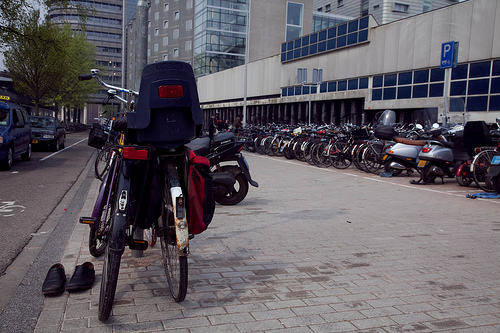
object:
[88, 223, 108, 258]
tire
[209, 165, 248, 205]
tire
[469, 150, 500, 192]
tire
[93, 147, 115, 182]
tire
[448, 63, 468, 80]
window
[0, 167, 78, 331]
road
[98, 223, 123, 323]
tire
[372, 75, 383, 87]
window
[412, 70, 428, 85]
window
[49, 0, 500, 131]
building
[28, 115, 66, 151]
car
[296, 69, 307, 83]
lights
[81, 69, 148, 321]
bicycle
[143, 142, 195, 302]
bicycle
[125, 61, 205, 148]
seat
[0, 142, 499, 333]
ground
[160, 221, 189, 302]
tire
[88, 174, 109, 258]
tire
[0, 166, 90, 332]
street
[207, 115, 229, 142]
man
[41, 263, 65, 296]
shoe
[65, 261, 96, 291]
shoe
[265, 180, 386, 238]
concrete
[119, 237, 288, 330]
shadow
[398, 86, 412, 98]
window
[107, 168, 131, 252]
fender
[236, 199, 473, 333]
street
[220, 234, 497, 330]
bricks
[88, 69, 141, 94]
handle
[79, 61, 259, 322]
back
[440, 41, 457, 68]
parking sign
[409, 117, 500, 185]
bike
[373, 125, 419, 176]
bike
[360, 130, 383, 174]
bike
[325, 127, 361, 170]
bike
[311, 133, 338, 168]
bike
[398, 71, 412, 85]
window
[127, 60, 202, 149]
backpack